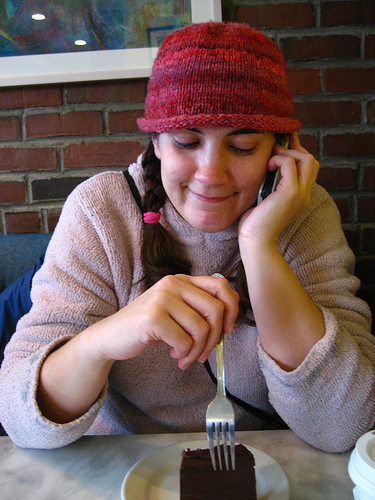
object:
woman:
[1, 17, 374, 453]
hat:
[135, 19, 301, 133]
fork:
[202, 272, 238, 472]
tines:
[205, 422, 216, 473]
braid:
[133, 135, 186, 288]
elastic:
[142, 206, 161, 226]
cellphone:
[255, 133, 291, 211]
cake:
[176, 441, 257, 500]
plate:
[119, 432, 293, 500]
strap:
[118, 165, 278, 427]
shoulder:
[65, 167, 144, 226]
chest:
[122, 220, 293, 352]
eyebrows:
[224, 127, 269, 140]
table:
[0, 428, 374, 499]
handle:
[207, 270, 232, 389]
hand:
[235, 128, 318, 250]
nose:
[194, 141, 228, 188]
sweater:
[0, 153, 373, 451]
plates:
[347, 427, 373, 499]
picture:
[1, 0, 225, 95]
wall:
[1, 1, 374, 329]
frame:
[0, 0, 223, 93]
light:
[27, 12, 45, 27]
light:
[73, 38, 87, 50]